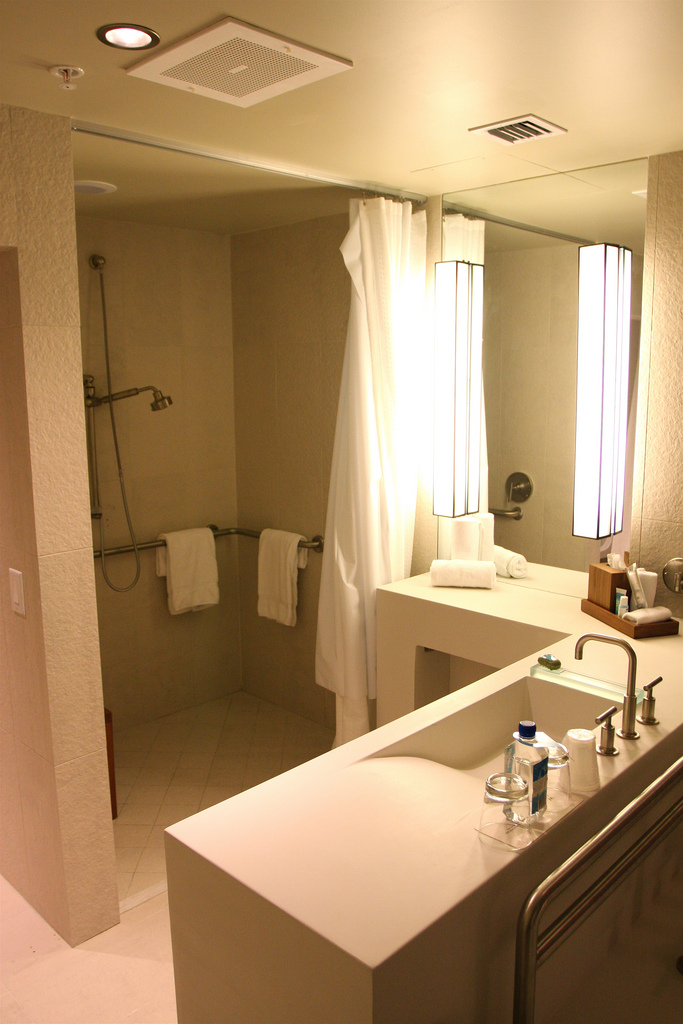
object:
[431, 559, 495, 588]
towel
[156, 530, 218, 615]
towel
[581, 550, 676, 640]
tissue box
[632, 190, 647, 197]
lights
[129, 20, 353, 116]
speaker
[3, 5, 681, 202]
ceiling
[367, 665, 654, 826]
sink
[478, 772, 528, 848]
glass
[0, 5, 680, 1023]
bathroom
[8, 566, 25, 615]
switch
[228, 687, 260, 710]
tile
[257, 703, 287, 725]
tile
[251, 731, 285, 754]
tile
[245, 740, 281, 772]
tile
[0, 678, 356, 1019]
floor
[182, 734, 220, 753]
tile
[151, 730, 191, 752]
tile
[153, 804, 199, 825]
tile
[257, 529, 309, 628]
towel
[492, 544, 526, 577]
towel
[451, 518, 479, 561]
towel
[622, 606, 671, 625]
towel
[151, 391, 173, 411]
head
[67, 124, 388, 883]
shower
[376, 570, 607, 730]
counter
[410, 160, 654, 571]
mirror